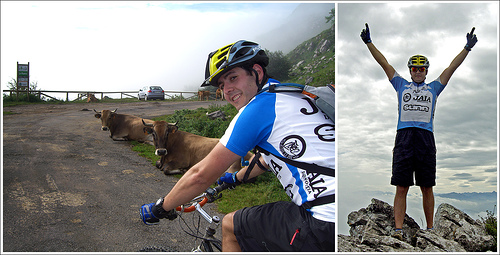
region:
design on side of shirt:
[264, 128, 313, 161]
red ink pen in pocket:
[279, 221, 309, 246]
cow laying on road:
[85, 101, 142, 146]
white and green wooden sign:
[9, 57, 39, 97]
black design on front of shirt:
[400, 92, 413, 103]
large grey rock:
[338, 198, 389, 249]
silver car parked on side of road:
[133, 86, 165, 105]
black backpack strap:
[285, 149, 332, 179]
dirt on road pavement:
[13, 163, 107, 228]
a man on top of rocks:
[352, 17, 464, 228]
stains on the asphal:
[20, 154, 100, 242]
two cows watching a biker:
[100, 104, 202, 165]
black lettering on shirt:
[400, 94, 440, 123]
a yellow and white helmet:
[200, 42, 251, 83]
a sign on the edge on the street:
[12, 55, 42, 100]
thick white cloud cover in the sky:
[455, 94, 491, 184]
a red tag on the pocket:
[292, 225, 297, 245]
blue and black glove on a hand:
[135, 197, 165, 223]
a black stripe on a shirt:
[286, 154, 336, 176]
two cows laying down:
[92, 107, 219, 173]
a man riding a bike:
[141, 37, 336, 252]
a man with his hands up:
[361, 23, 476, 230]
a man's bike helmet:
[200, 40, 270, 85]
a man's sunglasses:
[410, 63, 429, 74]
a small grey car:
[139, 84, 167, 101]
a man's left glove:
[140, 202, 168, 224]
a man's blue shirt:
[391, 79, 443, 130]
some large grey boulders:
[339, 200, 496, 249]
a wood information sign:
[15, 60, 29, 100]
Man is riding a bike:
[131, 40, 335, 253]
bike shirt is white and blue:
[217, 86, 339, 221]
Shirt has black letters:
[268, 91, 335, 200]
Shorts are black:
[392, 126, 434, 186]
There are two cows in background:
[94, 106, 215, 174]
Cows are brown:
[87, 107, 224, 172]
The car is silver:
[139, 86, 166, 98]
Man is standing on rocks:
[353, 21, 480, 253]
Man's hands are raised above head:
[356, 22, 480, 87]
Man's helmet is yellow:
[407, 56, 432, 66]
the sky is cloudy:
[356, 14, 434, 82]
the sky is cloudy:
[380, 10, 451, 71]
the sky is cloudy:
[382, 27, 482, 77]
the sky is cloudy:
[349, 25, 480, 157]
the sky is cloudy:
[380, 2, 477, 107]